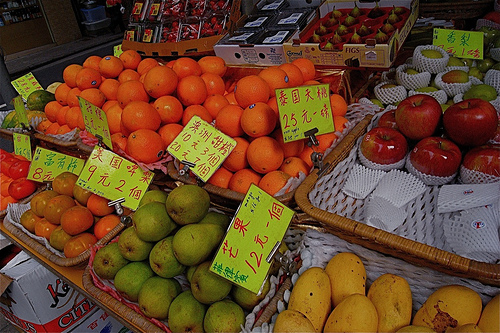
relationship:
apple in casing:
[358, 123, 410, 170] [358, 140, 408, 173]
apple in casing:
[406, 134, 465, 181] [403, 148, 460, 190]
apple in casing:
[461, 140, 499, 183] [457, 161, 500, 190]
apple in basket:
[440, 95, 499, 151] [289, 102, 500, 287]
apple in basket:
[375, 106, 404, 134] [289, 102, 500, 287]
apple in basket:
[392, 91, 446, 145] [289, 102, 500, 287]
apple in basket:
[358, 123, 410, 170] [289, 102, 500, 287]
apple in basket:
[406, 134, 465, 181] [289, 102, 500, 287]